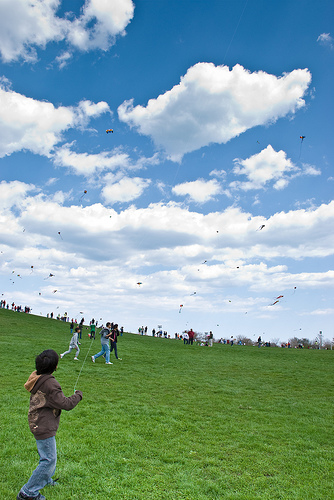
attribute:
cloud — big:
[1, 1, 130, 62]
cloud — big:
[115, 61, 308, 156]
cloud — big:
[3, 86, 109, 158]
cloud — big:
[238, 143, 299, 187]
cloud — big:
[22, 199, 327, 262]